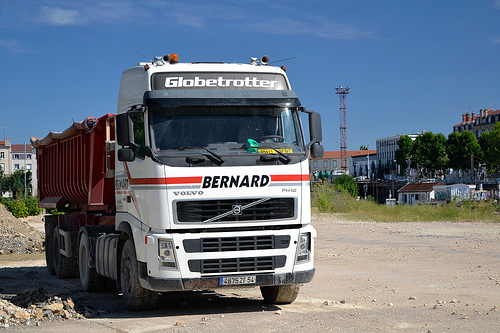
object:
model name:
[173, 188, 203, 196]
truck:
[30, 48, 323, 313]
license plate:
[219, 273, 259, 287]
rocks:
[408, 295, 424, 302]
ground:
[0, 217, 499, 332]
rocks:
[334, 299, 348, 307]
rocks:
[174, 320, 187, 328]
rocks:
[385, 302, 396, 309]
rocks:
[274, 308, 287, 318]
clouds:
[30, 0, 94, 29]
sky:
[1, 0, 498, 150]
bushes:
[1, 191, 49, 223]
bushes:
[327, 167, 365, 196]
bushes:
[313, 179, 356, 211]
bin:
[24, 108, 121, 213]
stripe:
[125, 173, 313, 185]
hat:
[239, 134, 274, 155]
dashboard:
[154, 137, 298, 160]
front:
[147, 67, 322, 293]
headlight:
[156, 232, 178, 275]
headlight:
[295, 232, 315, 267]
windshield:
[145, 95, 306, 168]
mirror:
[114, 144, 138, 164]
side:
[106, 95, 164, 258]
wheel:
[107, 234, 158, 311]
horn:
[159, 52, 176, 67]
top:
[123, 51, 299, 94]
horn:
[259, 54, 274, 67]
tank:
[125, 195, 133, 204]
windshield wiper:
[198, 144, 225, 163]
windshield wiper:
[259, 138, 291, 163]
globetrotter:
[161, 72, 286, 89]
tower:
[334, 82, 352, 182]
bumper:
[145, 265, 322, 292]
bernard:
[199, 171, 274, 189]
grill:
[162, 192, 297, 228]